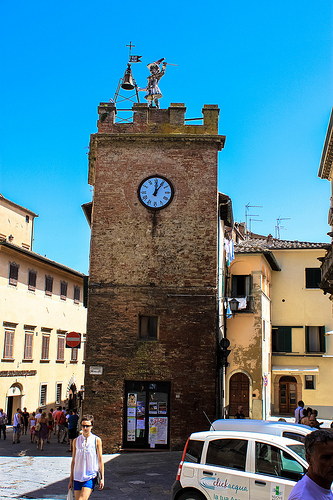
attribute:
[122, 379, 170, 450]
door — double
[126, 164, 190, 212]
clock — round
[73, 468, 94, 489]
shorts — blue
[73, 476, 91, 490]
shorts — blue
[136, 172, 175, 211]
clock — white, black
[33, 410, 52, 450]
woman — Walking 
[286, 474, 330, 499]
t-shirt — white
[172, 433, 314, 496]
car — white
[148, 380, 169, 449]
door — double 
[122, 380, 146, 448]
door — double 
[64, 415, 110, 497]
woman — cutely dressed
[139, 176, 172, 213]
clock — round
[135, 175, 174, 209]
clock — big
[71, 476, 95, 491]
shorts — blue jean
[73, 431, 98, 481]
shirt — white, flowy, cotton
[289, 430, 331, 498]
man — darker